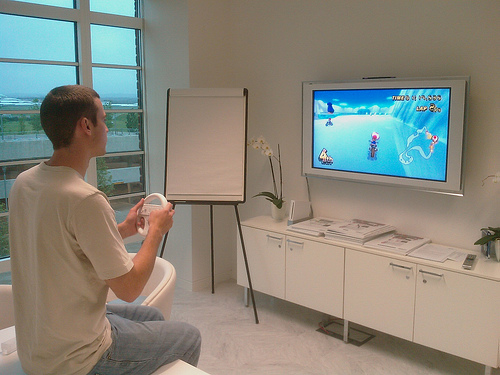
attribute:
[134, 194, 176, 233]
game controller — white, round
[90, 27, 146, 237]
window — small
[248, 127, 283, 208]
flowers — green, white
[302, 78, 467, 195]
tv — large, gray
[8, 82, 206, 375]
man — seated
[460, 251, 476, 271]
remote control — gray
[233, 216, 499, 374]
cabinet — white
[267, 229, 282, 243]
handle — gray, silver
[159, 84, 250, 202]
paper — white, large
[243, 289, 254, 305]
cabinet leg — silver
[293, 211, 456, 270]
papers — stacked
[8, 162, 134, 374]
shirt — white, beige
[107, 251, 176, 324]
chair — white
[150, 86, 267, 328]
easel — black, 3 legged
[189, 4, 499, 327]
wall — white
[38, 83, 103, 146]
hair — brown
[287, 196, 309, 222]
wii console — white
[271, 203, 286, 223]
vase — white